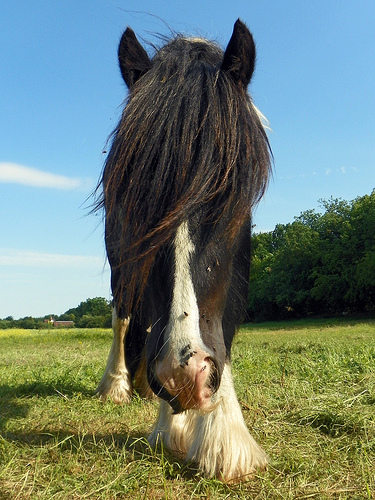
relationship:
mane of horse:
[85, 40, 274, 315] [97, 18, 273, 482]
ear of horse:
[118, 29, 153, 92] [97, 18, 273, 482]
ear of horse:
[221, 18, 256, 90] [97, 18, 273, 482]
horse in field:
[97, 18, 273, 482] [1, 319, 375, 499]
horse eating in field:
[97, 18, 273, 482] [1, 319, 375, 499]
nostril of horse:
[201, 356, 218, 390] [97, 18, 273, 482]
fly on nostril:
[183, 312, 189, 316] [146, 369, 164, 397]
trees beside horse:
[250, 190, 373, 319] [97, 18, 273, 482]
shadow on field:
[1, 381, 106, 450] [1, 319, 375, 499]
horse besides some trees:
[97, 18, 273, 482] [250, 190, 373, 319]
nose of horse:
[161, 370, 211, 409] [97, 18, 273, 482]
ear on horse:
[118, 29, 153, 92] [97, 18, 273, 482]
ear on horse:
[221, 18, 256, 90] [97, 18, 273, 482]